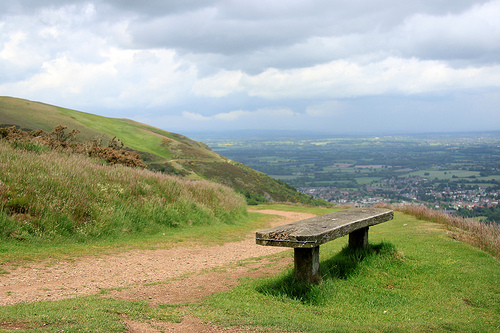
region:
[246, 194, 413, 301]
brown wooden bench on green grass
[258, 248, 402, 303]
shadow of a bench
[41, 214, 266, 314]
dirt road on a green hill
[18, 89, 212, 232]
green and brown hillside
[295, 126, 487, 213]
cityscape in the background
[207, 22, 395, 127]
white and grey clouds in a blue sky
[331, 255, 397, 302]
green grass on the ground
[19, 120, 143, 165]
brown bushes on a green hill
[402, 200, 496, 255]
brown weeds on a green hillside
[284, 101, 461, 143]
blue sky in the horizon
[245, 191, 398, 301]
a stone bench in a field.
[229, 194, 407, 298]
a bench on a hillside.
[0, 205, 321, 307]
a dirt road.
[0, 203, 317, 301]
A dirt road on a hillside.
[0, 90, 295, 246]
a long grass covered hillside.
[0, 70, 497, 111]
a large white and gray cloud.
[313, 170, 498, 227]
A city below a hillside.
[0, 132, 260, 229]
a dry grass covered hillside.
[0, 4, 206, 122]
a large gray cloud.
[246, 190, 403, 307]
a bench on a grass covered hillside.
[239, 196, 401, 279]
ths is a bench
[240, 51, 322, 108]
a cloud on the sky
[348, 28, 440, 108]
a cloud on the sky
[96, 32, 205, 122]
a cloud on the sky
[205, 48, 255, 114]
a cloud on the sky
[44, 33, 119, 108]
a cloud on the sky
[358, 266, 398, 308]
this is grass on the ground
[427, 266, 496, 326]
this is grass on the ground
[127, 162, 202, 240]
this is grass on the ground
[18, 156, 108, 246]
this is grass on the ground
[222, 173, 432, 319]
a wooden bench on the path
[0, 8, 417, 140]
large white clouds in the sky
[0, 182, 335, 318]
a walking path in front of bench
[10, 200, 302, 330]
a walking path in the grass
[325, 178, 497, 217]
lots of white houses in the distance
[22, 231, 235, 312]
a dirt path to walk on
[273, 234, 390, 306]
shadow cast under bench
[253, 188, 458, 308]
a bench in the grass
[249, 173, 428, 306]
a bench for taking a rest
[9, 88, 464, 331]
lots of grass on the ground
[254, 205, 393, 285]
bench is made of wood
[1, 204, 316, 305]
small dirt trail down the hill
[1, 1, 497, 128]
dark clouds cover the sky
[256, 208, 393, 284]
old worn out wooden bench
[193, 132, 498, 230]
small farm town below the hill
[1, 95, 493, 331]
green grass covers the hill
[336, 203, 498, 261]
brown dried out grass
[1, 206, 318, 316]
heavily walked on trail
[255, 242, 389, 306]
shadow under bench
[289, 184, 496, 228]
town below the hill